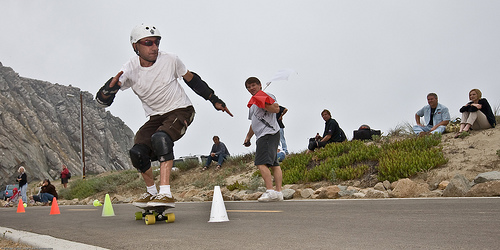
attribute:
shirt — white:
[114, 50, 192, 115]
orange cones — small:
[12, 195, 62, 217]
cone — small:
[208, 186, 228, 222]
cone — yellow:
[98, 197, 128, 232]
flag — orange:
[242, 87, 283, 119]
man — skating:
[63, 26, 221, 218]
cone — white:
[191, 173, 246, 236]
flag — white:
[249, 92, 273, 108]